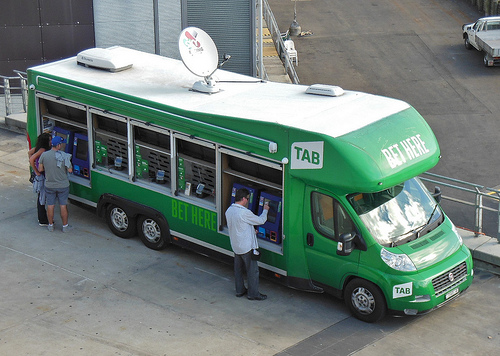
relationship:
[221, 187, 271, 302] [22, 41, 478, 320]
person by truck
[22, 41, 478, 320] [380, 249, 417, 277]
truck has a light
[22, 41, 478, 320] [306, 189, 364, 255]
truck has a window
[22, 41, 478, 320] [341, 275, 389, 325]
truck has a tire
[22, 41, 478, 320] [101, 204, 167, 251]
truck has back tires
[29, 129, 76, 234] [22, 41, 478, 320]
people by truck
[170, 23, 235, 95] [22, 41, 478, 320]
satelite on truck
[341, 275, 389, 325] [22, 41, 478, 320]
tire on truck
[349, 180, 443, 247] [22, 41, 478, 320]
windshield on truck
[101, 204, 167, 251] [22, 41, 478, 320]
tires on truck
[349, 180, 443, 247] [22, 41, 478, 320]
windshield of truck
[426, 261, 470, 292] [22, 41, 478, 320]
grill of truck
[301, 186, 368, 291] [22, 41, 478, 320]
door of truck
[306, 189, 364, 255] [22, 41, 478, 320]
window of truck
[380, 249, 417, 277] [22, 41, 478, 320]
light of truck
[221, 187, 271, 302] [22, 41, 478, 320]
man by truck